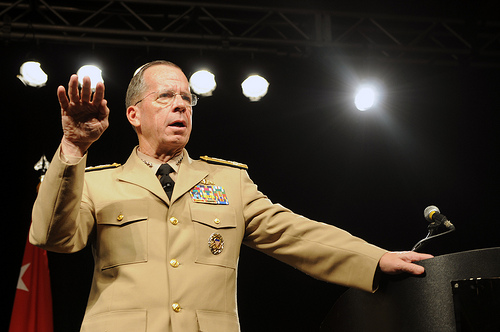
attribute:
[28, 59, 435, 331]
man — light-skinned, standing, speaking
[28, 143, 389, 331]
uniform — buttoned, brown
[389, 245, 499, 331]
podium — black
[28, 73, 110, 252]
arm — raised, bent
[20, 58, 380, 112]
lights — shiny, white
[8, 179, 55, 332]
flag — red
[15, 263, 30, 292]
design — white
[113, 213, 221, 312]
buttons — gold, brass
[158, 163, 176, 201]
tie — black, brown, dark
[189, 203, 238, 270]
pocket — buttoned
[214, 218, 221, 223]
button — gold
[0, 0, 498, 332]
blackdrop — black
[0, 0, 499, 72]
railing — metal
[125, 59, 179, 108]
hair — short